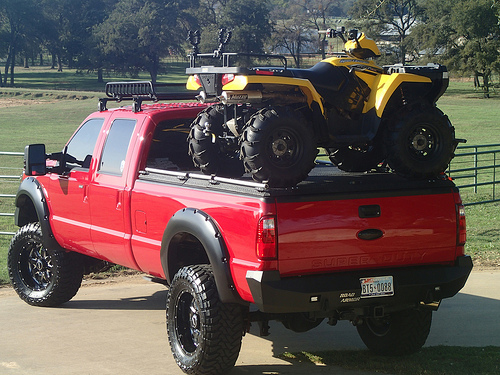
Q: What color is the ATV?
A: Yellow.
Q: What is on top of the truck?
A: An ATV.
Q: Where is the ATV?
A: On top of the truck.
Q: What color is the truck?
A: Red.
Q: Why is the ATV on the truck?
A: To be transported.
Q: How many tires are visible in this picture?
A: Seven.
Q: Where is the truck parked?
A: In a driveway.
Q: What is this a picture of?
A: An ATV on a truck.